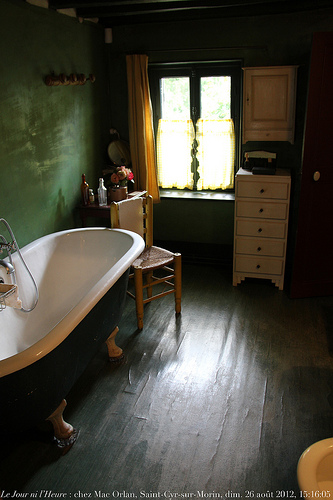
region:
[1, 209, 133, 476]
bath tub on floor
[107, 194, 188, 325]
a wooden chair with 4 leg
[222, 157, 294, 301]
a mini shelf on floor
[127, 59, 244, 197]
window of a restroom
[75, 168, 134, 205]
bottles on a table stand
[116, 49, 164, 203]
blinds of a window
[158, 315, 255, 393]
light from the window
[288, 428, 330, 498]
the toilet sink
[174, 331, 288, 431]
wooden floor of restroom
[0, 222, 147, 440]
bathtub has claw feet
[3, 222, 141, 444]
Bathtub has green exterior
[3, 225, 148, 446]
bathtub has white interior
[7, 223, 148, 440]
bathtub is made of porcelain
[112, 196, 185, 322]
chair is made of wood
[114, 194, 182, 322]
chair has wicker seat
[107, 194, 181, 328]
towel on back of chair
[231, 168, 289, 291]
wooden cabinet with drawers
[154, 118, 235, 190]
window has yellow curtains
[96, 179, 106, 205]
empty bottle on shelf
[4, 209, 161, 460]
a standalone bath tub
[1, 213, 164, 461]
the exterior of the tub is black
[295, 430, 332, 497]
edge of the toilet seat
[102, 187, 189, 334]
a wooden chair in a bathroom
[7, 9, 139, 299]
the wall in the bathroom is green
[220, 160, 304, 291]
a white drawer case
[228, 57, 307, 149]
a small wooden cabinet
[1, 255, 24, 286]
the water faucet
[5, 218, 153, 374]
the inside of the tub is white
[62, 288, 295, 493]
a faded wooden floor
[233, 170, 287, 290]
a tall white cabinet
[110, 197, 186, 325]
a brown wicker chair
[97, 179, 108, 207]
an empty liquor bottle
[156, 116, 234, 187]
a pair of curtains leaking light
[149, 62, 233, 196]
a window partially covered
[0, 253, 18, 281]
the spout of a bathtup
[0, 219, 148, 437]
a long traditional bathtub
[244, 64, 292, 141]
a wooden white cabinet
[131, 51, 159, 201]
a long yellow curtain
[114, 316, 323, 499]
a black wooden floor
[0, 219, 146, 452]
an old claw foot tub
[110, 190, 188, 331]
a wooden chair next to the tub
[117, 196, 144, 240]
a small white towel draped on the back of the chair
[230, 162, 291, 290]
a white chest of drawers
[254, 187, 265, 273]
circular black handles on the drawers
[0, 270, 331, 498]
an old hardwood floor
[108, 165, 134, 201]
a cup with pink flowers in it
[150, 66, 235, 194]
a small window with curtains on the bottom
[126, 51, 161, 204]
a yellow curtain on the left side of the window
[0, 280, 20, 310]
a soap holder in the tub